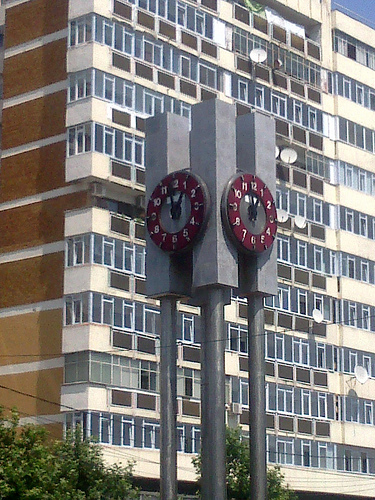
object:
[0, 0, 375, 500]
building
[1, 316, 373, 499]
power lines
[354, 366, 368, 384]
dish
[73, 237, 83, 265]
white curtain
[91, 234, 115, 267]
window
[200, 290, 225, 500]
pole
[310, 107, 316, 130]
window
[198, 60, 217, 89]
window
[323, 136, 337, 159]
ground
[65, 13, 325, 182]
windows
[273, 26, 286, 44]
cloth hanging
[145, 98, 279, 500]
tower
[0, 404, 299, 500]
trees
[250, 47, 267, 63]
satellite dish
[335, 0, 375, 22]
sky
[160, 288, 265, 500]
iron columns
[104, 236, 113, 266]
window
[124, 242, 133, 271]
window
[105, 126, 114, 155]
window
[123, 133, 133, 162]
window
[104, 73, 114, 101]
window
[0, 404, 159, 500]
trees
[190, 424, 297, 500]
trees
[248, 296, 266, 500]
pole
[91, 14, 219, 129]
windows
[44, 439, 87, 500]
leaves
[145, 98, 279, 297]
clock tower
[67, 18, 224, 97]
wall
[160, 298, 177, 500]
pole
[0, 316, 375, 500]
electrical lines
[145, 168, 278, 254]
clocks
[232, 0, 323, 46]
porch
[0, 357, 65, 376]
stripe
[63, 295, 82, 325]
window